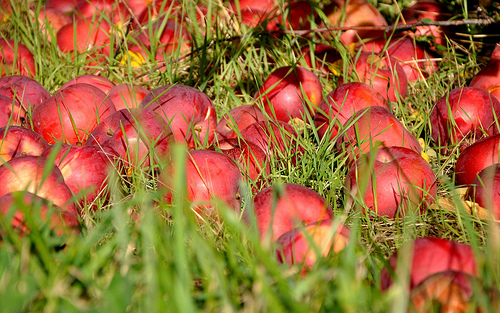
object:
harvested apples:
[1, 0, 475, 310]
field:
[0, 0, 500, 313]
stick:
[132, 22, 425, 83]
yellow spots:
[307, 225, 343, 259]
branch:
[129, 17, 500, 82]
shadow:
[180, 29, 344, 97]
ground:
[1, 3, 497, 311]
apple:
[41, 143, 122, 213]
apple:
[0, 154, 76, 219]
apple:
[136, 82, 217, 146]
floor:
[0, 0, 500, 313]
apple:
[240, 182, 334, 244]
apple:
[29, 78, 118, 146]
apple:
[378, 238, 483, 295]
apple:
[238, 119, 303, 170]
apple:
[340, 51, 408, 104]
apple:
[57, 14, 115, 68]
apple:
[254, 66, 324, 124]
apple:
[85, 108, 177, 172]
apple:
[345, 143, 437, 218]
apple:
[156, 149, 243, 225]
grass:
[0, 0, 499, 313]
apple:
[426, 86, 500, 151]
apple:
[277, 218, 358, 271]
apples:
[53, 20, 118, 61]